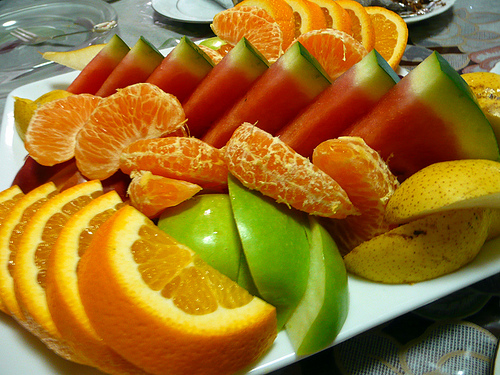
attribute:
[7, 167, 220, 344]
orange — small, fresh, slices, peeled, peel, slice, sliced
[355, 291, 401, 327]
plate — dinner, square, white, assorted, clear, edge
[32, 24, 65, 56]
fork — dinner, silve, metal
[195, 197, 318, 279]
apple — golden, green, fruit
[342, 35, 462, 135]
meleon — apple, red, water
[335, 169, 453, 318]
lemon — wedges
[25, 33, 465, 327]
fruit — flavors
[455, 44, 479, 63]
table — pattern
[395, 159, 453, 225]
pear — yellow, brown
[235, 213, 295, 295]
rine — green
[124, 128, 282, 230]
clementine — sections, section